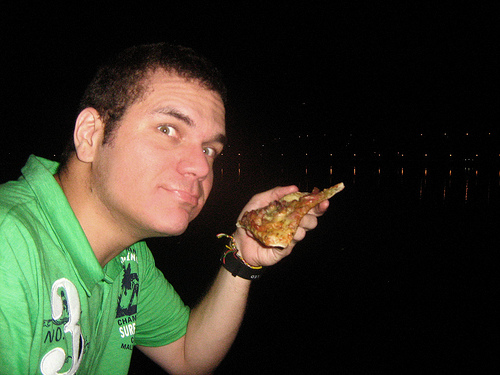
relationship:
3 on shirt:
[37, 274, 84, 374] [7, 161, 187, 364]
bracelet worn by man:
[209, 232, 270, 281] [5, 47, 345, 374]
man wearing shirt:
[5, 47, 345, 374] [11, 233, 148, 368]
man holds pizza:
[5, 47, 342, 374] [227, 161, 374, 280]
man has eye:
[5, 47, 342, 374] [154, 123, 186, 143]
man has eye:
[5, 47, 342, 374] [201, 134, 219, 161]